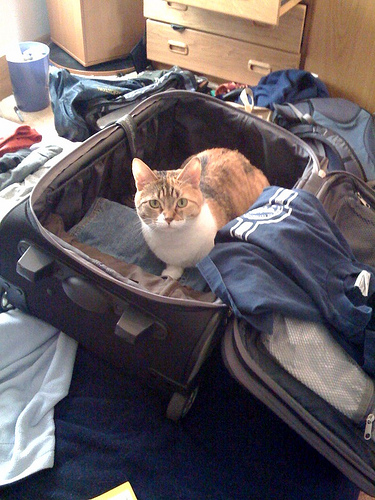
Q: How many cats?
A: 1.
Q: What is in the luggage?
A: Cat.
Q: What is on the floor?
A: Clothes.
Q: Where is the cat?
A: Luggage.